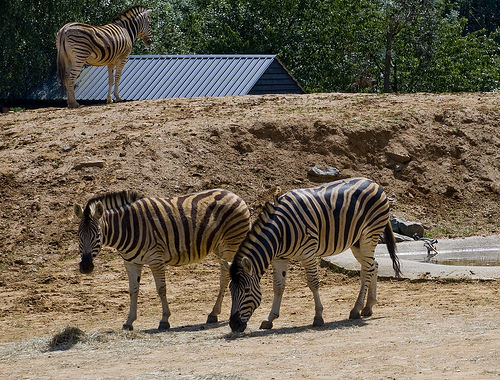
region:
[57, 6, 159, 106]
Zebra standing on hilly ground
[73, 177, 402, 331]
Two zebras walking on dirt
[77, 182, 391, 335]
Zebras covered with dirt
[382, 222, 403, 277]
Brown tail of zebra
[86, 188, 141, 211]
Striped mane of zebra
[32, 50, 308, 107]
Building with iron sheet rooftop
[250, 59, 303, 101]
Building made of wood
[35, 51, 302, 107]
Building painted in blue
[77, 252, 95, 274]
Black mouth of zebra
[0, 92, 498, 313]
Ground covered with mad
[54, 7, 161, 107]
blue tile roof black and white zebra on a little mountain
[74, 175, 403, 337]
two zebras walking together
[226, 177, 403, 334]
black and white zebra looking down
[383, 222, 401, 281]
hairy black tail of zebra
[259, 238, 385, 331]
four legs of zebra in front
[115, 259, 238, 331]
four legs of zebra behind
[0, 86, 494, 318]
little dirt mountain behind zebras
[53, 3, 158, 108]
zebra on his back on the mountain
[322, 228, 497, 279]
pavement little pond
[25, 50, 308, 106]
blue roof of a house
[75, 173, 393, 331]
two zebras in an enclosure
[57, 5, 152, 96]
zebra standing on top of hill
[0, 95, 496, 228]
pile of dirt with no grass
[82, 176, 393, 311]
zebras are brown and dirty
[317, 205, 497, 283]
a watering hole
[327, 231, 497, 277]
cement basin is foundation for watering hole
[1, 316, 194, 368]
brown dry grass at bottom left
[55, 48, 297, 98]
the top of a shed behind the hill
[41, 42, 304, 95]
roof of shed is metal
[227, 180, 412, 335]
zebra at right is eating dry grass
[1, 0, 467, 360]
three zebras in a pen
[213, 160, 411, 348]
zebra is eating from ground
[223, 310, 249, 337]
muzzle of zebra is black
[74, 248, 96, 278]
muzzle of zebra is black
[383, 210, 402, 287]
tail of zebra is long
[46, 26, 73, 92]
tail of zebra is long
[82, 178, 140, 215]
man of zebra is white and black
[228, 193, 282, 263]
man of zebra is white and black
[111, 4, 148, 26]
man of zebra is white and black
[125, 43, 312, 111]
roof of home is black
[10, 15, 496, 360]
a scene during the day time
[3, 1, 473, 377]
a scene outside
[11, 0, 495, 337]
a scene at the zoo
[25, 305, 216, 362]
hay on the ground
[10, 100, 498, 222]
a dirt hill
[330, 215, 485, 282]
water in a pool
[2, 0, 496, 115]
green trees in the background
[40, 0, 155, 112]
a zebra on a hill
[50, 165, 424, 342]
a couple of zebras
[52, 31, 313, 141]
a blue roof to a building